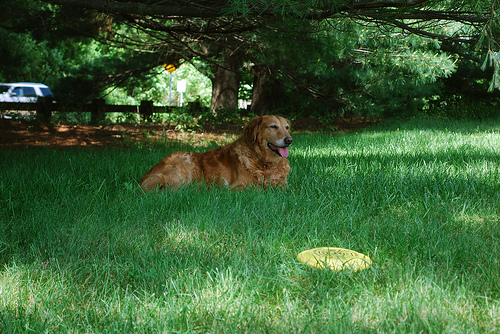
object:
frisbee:
[294, 245, 372, 273]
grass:
[1, 141, 499, 332]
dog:
[135, 115, 296, 189]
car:
[0, 80, 54, 105]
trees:
[88, 1, 363, 115]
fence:
[1, 98, 207, 129]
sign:
[164, 57, 189, 110]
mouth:
[268, 144, 293, 160]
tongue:
[278, 147, 293, 158]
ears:
[247, 116, 262, 144]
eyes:
[266, 124, 281, 130]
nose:
[282, 132, 295, 146]